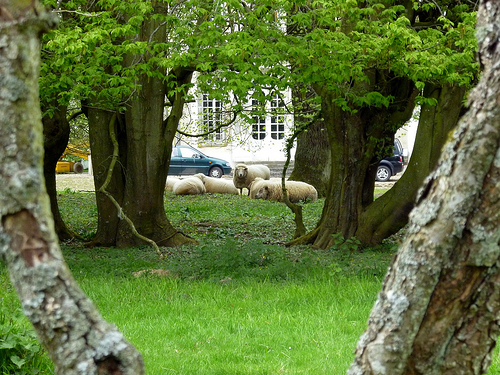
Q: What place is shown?
A: It is a park.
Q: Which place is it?
A: It is a park.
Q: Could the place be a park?
A: Yes, it is a park.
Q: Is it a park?
A: Yes, it is a park.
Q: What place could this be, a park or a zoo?
A: It is a park.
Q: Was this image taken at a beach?
A: No, the picture was taken in a park.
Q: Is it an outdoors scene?
A: Yes, it is outdoors.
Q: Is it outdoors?
A: Yes, it is outdoors.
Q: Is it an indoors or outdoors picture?
A: It is outdoors.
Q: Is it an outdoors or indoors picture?
A: It is outdoors.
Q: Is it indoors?
A: No, it is outdoors.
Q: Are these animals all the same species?
A: Yes, all the animals are sheep.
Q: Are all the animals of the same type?
A: Yes, all the animals are sheep.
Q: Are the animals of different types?
A: No, all the animals are sheep.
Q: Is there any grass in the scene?
A: Yes, there is grass.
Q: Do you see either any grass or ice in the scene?
A: Yes, there is grass.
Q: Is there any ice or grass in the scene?
A: Yes, there is grass.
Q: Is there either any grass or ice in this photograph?
A: Yes, there is grass.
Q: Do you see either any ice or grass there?
A: Yes, there is grass.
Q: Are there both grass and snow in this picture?
A: No, there is grass but no snow.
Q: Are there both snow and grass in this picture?
A: No, there is grass but no snow.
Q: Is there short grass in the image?
A: Yes, there is short grass.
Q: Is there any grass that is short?
A: Yes, there is grass that is short.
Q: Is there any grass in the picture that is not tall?
A: Yes, there is short grass.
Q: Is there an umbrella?
A: No, there are no umbrellas.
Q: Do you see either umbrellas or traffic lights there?
A: No, there are no umbrellas or traffic lights.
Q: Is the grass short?
A: Yes, the grass is short.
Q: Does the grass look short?
A: Yes, the grass is short.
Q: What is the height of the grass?
A: The grass is short.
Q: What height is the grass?
A: The grass is short.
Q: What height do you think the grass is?
A: The grass is short.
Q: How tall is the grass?
A: The grass is short.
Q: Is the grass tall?
A: No, the grass is short.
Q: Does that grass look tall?
A: No, the grass is short.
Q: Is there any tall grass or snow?
A: No, there is grass but it is short.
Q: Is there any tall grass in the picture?
A: No, there is grass but it is short.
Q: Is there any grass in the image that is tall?
A: No, there is grass but it is short.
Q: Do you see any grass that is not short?
A: No, there is grass but it is short.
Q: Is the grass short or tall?
A: The grass is short.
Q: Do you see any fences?
A: No, there are no fences.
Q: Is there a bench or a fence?
A: No, there are no fences or benches.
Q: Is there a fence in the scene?
A: No, there are no fences.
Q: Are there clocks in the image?
A: No, there are no clocks.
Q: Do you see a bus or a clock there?
A: No, there are no clocks or buses.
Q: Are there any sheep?
A: Yes, there is a sheep.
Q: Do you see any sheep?
A: Yes, there is a sheep.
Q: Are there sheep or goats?
A: Yes, there is a sheep.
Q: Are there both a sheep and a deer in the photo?
A: No, there is a sheep but no deer.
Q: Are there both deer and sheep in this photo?
A: No, there is a sheep but no deer.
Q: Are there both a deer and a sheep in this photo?
A: No, there is a sheep but no deer.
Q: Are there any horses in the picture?
A: No, there are no horses.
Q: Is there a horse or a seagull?
A: No, there are no horses or seagulls.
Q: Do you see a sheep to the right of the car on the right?
A: No, the sheep is to the left of the car.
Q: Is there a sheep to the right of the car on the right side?
A: No, the sheep is to the left of the car.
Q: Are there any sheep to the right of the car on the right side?
A: No, the sheep is to the left of the car.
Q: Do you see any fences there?
A: No, there are no fences.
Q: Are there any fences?
A: No, there are no fences.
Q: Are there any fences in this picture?
A: No, there are no fences.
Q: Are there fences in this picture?
A: No, there are no fences.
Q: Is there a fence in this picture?
A: No, there are no fences.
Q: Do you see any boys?
A: No, there are no boys.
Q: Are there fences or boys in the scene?
A: No, there are no boys or fences.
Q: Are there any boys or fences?
A: No, there are no boys or fences.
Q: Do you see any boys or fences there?
A: No, there are no boys or fences.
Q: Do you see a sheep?
A: Yes, there is a sheep.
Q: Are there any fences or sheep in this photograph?
A: Yes, there is a sheep.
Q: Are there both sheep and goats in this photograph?
A: No, there is a sheep but no goats.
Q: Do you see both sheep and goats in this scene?
A: No, there is a sheep but no goats.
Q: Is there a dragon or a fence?
A: No, there are no fences or dragons.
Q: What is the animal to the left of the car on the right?
A: The animal is a sheep.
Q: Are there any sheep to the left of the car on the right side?
A: Yes, there is a sheep to the left of the car.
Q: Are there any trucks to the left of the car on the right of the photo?
A: No, there is a sheep to the left of the car.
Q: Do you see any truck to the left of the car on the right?
A: No, there is a sheep to the left of the car.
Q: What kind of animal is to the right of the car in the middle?
A: The animal is a sheep.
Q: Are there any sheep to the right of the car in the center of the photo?
A: Yes, there is a sheep to the right of the car.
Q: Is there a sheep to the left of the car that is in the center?
A: No, the sheep is to the right of the car.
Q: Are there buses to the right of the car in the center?
A: No, there is a sheep to the right of the car.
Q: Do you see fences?
A: No, there are no fences.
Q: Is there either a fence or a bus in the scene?
A: No, there are no fences or buses.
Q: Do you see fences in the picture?
A: No, there are no fences.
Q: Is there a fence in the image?
A: No, there are no fences.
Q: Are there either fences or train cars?
A: No, there are no fences or train cars.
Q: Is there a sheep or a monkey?
A: Yes, there is a sheep.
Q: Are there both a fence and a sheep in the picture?
A: No, there is a sheep but no fences.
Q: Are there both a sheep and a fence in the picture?
A: No, there is a sheep but no fences.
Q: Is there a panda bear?
A: No, there are no panda bears.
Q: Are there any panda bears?
A: No, there are no panda bears.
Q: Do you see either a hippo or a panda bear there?
A: No, there are no panda bears or hippoes.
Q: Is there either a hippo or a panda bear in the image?
A: No, there are no panda bears or hippoes.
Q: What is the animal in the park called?
A: The animal is a sheep.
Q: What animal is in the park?
A: The animal is a sheep.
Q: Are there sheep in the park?
A: Yes, there is a sheep in the park.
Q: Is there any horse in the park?
A: No, there is a sheep in the park.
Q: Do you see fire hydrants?
A: No, there are no fire hydrants.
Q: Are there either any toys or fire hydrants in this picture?
A: No, there are no fire hydrants or toys.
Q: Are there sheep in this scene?
A: Yes, there is a sheep.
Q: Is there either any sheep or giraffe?
A: Yes, there is a sheep.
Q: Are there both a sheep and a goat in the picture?
A: No, there is a sheep but no goats.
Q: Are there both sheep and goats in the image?
A: No, there is a sheep but no goats.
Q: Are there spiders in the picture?
A: No, there are no spiders.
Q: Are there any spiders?
A: No, there are no spiders.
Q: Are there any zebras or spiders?
A: No, there are no spiders or zebras.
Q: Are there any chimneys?
A: No, there are no chimneys.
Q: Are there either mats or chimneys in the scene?
A: No, there are no chimneys or mats.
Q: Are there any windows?
A: Yes, there is a window.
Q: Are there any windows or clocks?
A: Yes, there is a window.